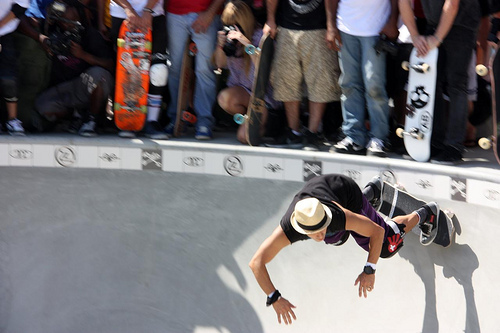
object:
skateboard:
[110, 10, 153, 133]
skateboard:
[400, 30, 446, 165]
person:
[210, 2, 265, 143]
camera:
[218, 18, 243, 58]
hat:
[285, 196, 336, 242]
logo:
[384, 232, 406, 258]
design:
[136, 145, 169, 176]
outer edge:
[1, 134, 495, 214]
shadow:
[387, 231, 485, 332]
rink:
[4, 129, 499, 331]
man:
[247, 178, 443, 326]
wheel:
[233, 110, 248, 128]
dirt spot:
[368, 84, 394, 113]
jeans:
[329, 26, 393, 146]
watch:
[362, 263, 375, 278]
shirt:
[276, 170, 363, 246]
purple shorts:
[324, 193, 389, 254]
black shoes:
[365, 177, 441, 250]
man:
[320, 0, 402, 160]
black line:
[294, 212, 331, 232]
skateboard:
[364, 177, 461, 258]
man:
[391, 2, 478, 173]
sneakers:
[250, 125, 333, 152]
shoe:
[429, 140, 465, 171]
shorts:
[266, 22, 343, 110]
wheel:
[473, 63, 488, 79]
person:
[103, 1, 173, 144]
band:
[140, 6, 160, 18]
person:
[261, 0, 345, 148]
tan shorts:
[255, 21, 342, 112]